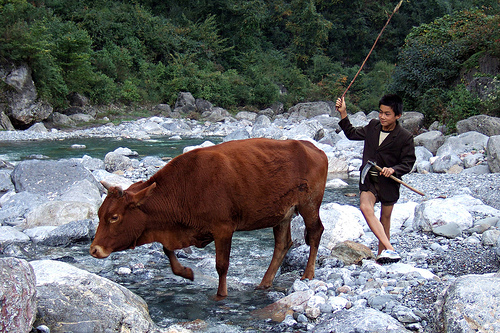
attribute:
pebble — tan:
[184, 317, 210, 331]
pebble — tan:
[337, 286, 349, 293]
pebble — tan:
[269, 307, 285, 324]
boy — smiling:
[329, 86, 416, 262]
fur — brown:
[187, 149, 314, 241]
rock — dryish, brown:
[328, 231, 378, 264]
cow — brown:
[70, 137, 332, 309]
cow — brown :
[88, 138, 335, 298]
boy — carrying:
[316, 89, 427, 279]